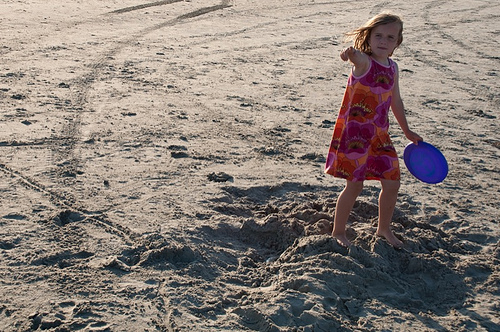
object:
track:
[8, 132, 180, 264]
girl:
[330, 12, 422, 247]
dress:
[324, 55, 401, 182]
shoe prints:
[218, 186, 251, 199]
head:
[353, 12, 402, 56]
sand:
[250, 257, 443, 318]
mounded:
[215, 252, 362, 329]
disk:
[402, 141, 451, 185]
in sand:
[0, 195, 198, 329]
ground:
[4, 193, 221, 327]